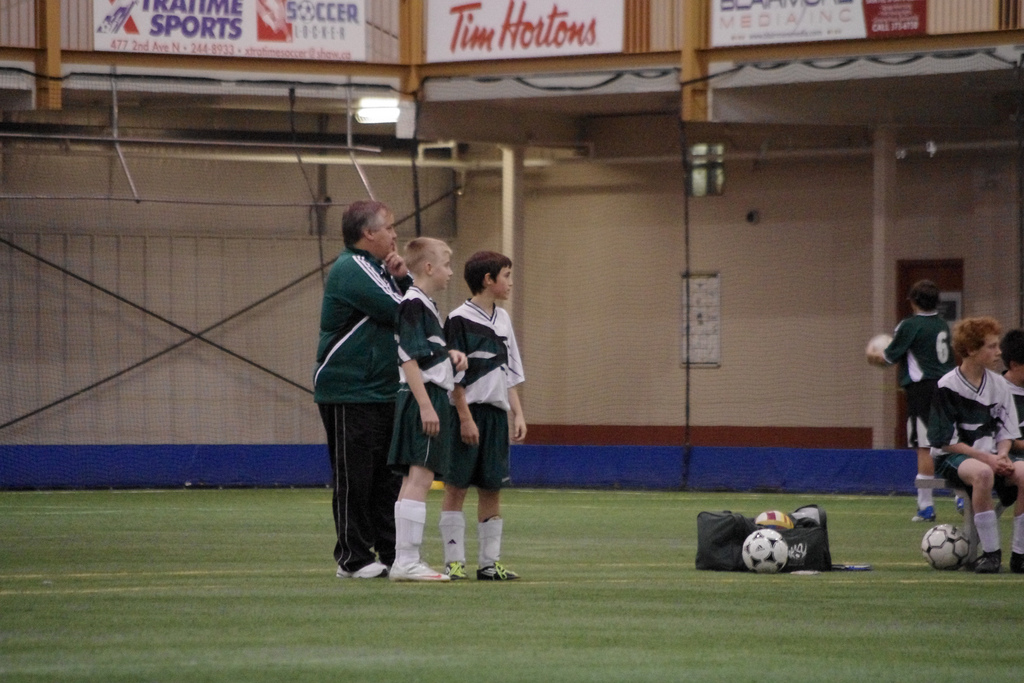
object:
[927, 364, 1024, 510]
uniforms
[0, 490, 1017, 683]
soccer field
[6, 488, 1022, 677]
grass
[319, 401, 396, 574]
pants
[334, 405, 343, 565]
stripes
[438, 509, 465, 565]
sock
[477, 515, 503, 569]
sock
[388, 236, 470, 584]
boy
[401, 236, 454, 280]
hair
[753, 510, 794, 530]
soccer ball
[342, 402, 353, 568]
stripes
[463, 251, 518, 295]
hair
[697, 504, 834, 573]
bag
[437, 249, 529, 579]
boy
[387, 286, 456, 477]
uniform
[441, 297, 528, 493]
uniform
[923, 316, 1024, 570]
athlete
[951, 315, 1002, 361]
hair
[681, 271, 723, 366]
poster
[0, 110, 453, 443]
wall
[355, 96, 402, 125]
light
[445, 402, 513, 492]
shorts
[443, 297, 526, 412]
shirt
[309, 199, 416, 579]
man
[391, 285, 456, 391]
shirt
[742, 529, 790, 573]
ball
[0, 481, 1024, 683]
ground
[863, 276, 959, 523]
athlete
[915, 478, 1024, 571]
bench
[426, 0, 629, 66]
signs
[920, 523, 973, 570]
ball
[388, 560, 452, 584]
sneakers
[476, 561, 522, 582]
shoelaces